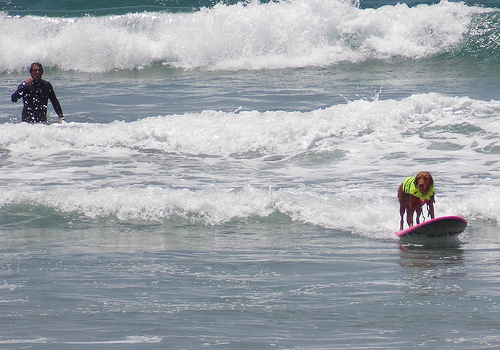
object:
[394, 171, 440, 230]
dog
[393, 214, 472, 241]
surfboard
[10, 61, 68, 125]
man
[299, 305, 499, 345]
water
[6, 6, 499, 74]
wave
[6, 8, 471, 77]
ocean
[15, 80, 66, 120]
wetsuit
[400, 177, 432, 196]
vest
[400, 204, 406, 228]
leg